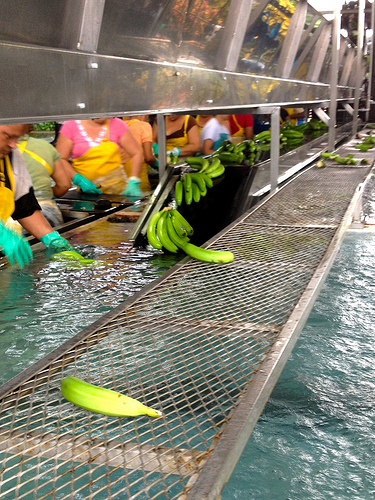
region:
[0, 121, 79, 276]
person washing a banana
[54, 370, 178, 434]
banana on the metal grate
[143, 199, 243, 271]
bunch of green bananas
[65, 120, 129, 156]
person wearing a pink shirt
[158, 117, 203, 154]
person in a yellow apron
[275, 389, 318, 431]
black in the water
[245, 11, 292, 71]
reflection in the window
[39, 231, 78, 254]
gloves the person is wearing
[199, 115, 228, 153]
woman in a white shirt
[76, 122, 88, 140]
white dots on the shirt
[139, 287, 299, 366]
large silver iron grate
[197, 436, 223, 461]
small amount of brown rust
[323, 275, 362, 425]
large body of water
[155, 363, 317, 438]
large fish swimming in the water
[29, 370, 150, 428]
single banana on grate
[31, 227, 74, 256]
green glove on woman's hand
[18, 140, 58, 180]
yellow strap over shoulder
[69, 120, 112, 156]
white design around neck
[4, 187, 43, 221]
black sleeve on black shirt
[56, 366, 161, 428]
banana on the shelf.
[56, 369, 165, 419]
the banana is green and yellow.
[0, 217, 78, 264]
people are wearing gloves.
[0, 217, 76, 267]
the gloves are teal.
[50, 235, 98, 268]
person rinsing the banana in water.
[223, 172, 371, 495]
the water is blue.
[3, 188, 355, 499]
metal shelf over the water.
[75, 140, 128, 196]
person wearing yellow apron.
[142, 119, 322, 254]
bananas on a track.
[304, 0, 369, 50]
the lights are on.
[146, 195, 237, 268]
green bananas on a rack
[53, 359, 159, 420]
banana over water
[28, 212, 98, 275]
worker washing bananas in the water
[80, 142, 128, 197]
person wearing a yellow apron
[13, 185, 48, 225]
person with black sleeves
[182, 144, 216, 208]
bananas on in the basket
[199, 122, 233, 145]
woman wearing a white tee shirt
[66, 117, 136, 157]
woman wearing a pink shirt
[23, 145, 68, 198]
woman wearing a green shirt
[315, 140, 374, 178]
bananas on the rack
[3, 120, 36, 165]
the head of a woman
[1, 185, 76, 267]
the hand of a woman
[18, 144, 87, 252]
the arm of a woman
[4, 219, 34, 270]
a woman wearing gloves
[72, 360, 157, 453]
a banana on a eack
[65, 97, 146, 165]
a woman wearing a shirt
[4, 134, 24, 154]
the nose of a woman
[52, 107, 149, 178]
a woman with a pink shirt on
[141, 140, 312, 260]
bananas in a bucket